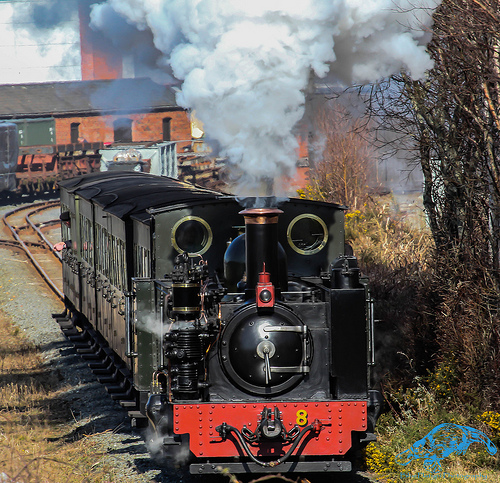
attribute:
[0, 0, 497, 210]
cloud — smoke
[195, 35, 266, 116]
smoke — cloud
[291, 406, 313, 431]
number — 8, yellow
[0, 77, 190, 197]
building — red, brick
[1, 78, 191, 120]
roof — black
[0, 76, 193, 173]
building — red, brick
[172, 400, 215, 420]
bolts — tiny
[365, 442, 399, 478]
leaves — yellow, tiny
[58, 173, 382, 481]
train — red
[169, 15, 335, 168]
cloud — smoke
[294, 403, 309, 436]
number — large, yellow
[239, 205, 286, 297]
stack — smoke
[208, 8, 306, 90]
smoke — cloud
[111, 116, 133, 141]
door — tall, black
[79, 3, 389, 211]
smoke — white, large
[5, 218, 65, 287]
rails — steel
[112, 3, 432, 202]
smoke — cloud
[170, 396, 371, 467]
bumper — red